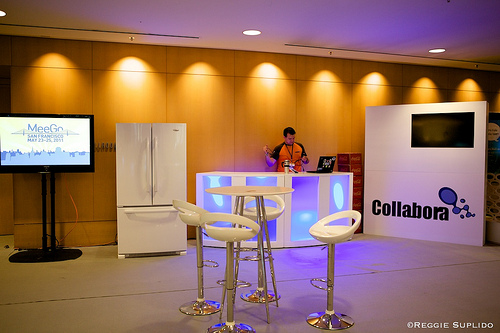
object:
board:
[362, 101, 486, 248]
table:
[198, 180, 304, 328]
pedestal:
[9, 169, 82, 264]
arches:
[0, 30, 500, 115]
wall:
[0, 10, 500, 250]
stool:
[304, 210, 361, 329]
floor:
[0, 232, 500, 333]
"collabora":
[372, 199, 450, 221]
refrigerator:
[114, 121, 188, 258]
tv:
[0, 113, 97, 174]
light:
[242, 29, 261, 36]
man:
[263, 126, 310, 172]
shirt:
[271, 141, 309, 172]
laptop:
[306, 156, 337, 174]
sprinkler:
[128, 36, 135, 41]